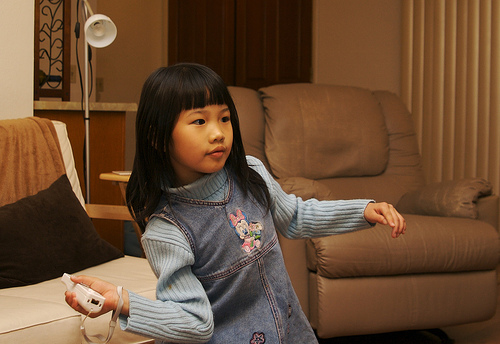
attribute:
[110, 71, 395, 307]
girl — white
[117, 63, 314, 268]
girl — young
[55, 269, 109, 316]
game controller — white, plastic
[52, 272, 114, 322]
remote — wii remote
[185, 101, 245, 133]
eyes — white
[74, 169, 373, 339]
dress — blue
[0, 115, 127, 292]
blanket — two-colored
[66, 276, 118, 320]
hand — long sleeved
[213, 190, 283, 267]
patch — embroidered, minnie mouse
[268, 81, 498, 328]
recliner — beige, leather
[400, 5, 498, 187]
blind — long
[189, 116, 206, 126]
eye — little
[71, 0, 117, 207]
columnlamp — white, plastic, metal, floor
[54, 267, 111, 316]
wii remote — white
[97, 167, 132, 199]
table — wooden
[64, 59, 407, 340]
girl — little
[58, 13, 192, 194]
lamp — blue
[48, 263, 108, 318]
remote — white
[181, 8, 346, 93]
doors — wooden, cabinet doors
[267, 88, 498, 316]
chair — leather, vinyl reclining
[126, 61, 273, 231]
hair — black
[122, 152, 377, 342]
garment — blue